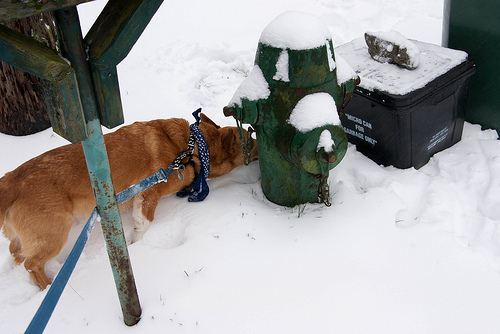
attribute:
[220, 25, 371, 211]
hydrant — green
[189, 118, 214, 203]
leash — blue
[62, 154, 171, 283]
leash — blue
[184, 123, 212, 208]
collar — blue, white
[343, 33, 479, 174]
box — plastic, black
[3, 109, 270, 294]
dog — sniffing, brown, smelling, standing, out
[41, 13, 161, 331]
posts — green, rusted, stuck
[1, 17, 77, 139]
stump — brown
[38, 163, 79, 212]
fur — golden